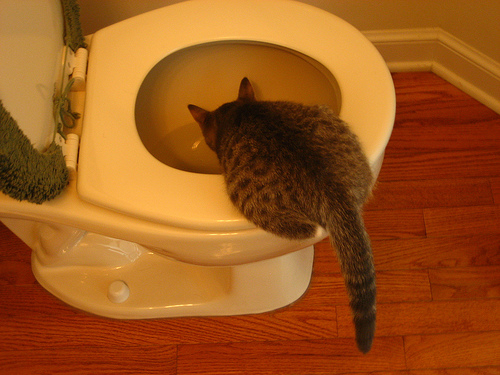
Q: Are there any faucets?
A: No, there are no faucets.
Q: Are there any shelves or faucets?
A: No, there are no faucets or shelves.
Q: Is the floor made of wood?
A: Yes, the floor is made of wood.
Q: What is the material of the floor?
A: The floor is made of wood.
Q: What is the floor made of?
A: The floor is made of wood.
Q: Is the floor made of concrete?
A: No, the floor is made of wood.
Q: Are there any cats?
A: Yes, there is a cat.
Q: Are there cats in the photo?
A: Yes, there is a cat.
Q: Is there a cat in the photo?
A: Yes, there is a cat.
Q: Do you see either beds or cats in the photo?
A: Yes, there is a cat.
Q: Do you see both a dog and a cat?
A: No, there is a cat but no dogs.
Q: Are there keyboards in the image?
A: No, there are no keyboards.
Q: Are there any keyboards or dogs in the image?
A: No, there are no keyboards or dogs.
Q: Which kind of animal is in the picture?
A: The animal is a cat.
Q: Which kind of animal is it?
A: The animal is a cat.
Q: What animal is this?
A: This is a cat.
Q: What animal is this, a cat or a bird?
A: This is a cat.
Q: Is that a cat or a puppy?
A: That is a cat.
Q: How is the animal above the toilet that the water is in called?
A: The animal is a cat.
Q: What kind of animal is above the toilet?
A: The animal is a cat.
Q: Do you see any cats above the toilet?
A: Yes, there is a cat above the toilet.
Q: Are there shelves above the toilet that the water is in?
A: No, there is a cat above the toilet.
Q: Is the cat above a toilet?
A: Yes, the cat is above a toilet.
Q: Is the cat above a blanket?
A: No, the cat is above a toilet.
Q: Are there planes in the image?
A: No, there are no planes.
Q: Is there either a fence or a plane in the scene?
A: No, there are no airplanes or fences.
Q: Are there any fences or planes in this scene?
A: No, there are no planes or fences.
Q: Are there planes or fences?
A: No, there are no planes or fences.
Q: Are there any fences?
A: No, there are no fences.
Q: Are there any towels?
A: No, there are no towels.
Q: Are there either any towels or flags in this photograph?
A: No, there are no towels or flags.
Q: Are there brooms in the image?
A: No, there are no brooms.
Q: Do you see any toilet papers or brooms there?
A: No, there are no brooms or toilet papers.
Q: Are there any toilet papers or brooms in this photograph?
A: No, there are no brooms or toilet papers.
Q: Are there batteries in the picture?
A: No, there are no batteries.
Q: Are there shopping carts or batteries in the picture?
A: No, there are no batteries or shopping carts.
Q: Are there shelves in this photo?
A: No, there are no shelves.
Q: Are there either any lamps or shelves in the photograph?
A: No, there are no shelves or lamps.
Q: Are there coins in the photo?
A: No, there are no coins.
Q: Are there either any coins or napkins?
A: No, there are no coins or napkins.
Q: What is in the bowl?
A: The water is in the bowl.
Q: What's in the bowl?
A: The water is in the bowl.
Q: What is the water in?
A: The water is in the bowl.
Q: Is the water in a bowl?
A: Yes, the water is in a bowl.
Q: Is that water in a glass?
A: No, the water is in a bowl.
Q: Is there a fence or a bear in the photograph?
A: No, there are no fences or bears.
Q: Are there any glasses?
A: No, there are no glasses.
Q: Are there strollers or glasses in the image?
A: No, there are no glasses or strollers.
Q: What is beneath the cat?
A: The toilet is beneath the cat.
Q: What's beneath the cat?
A: The toilet is beneath the cat.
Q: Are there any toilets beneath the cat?
A: Yes, there is a toilet beneath the cat.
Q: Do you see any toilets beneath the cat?
A: Yes, there is a toilet beneath the cat.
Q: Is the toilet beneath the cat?
A: Yes, the toilet is beneath the cat.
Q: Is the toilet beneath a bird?
A: No, the toilet is beneath the cat.